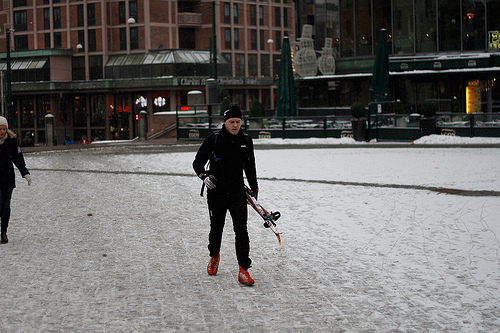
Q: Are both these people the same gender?
A: No, they are both male and female.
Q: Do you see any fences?
A: Yes, there is a fence.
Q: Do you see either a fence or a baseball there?
A: Yes, there is a fence.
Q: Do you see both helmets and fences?
A: No, there is a fence but no helmets.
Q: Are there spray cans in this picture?
A: No, there are no spray cans.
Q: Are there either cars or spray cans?
A: No, there are no spray cans or cars.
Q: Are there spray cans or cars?
A: No, there are no spray cans or cars.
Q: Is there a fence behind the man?
A: Yes, there is a fence behind the man.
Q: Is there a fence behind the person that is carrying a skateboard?
A: Yes, there is a fence behind the man.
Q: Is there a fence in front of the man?
A: No, the fence is behind the man.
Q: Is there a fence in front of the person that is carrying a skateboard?
A: No, the fence is behind the man.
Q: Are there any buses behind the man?
A: No, there is a fence behind the man.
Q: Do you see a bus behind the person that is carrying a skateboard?
A: No, there is a fence behind the man.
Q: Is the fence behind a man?
A: Yes, the fence is behind a man.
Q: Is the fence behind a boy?
A: No, the fence is behind a man.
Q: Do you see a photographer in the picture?
A: No, there are no photographers.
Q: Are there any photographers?
A: No, there are no photographers.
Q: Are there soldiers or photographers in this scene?
A: No, there are no photographers or soldiers.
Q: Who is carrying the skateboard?
A: The man is carrying the skateboard.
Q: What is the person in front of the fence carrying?
A: The man is carrying a skateboard.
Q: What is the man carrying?
A: The man is carrying a skateboard.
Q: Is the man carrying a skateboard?
A: Yes, the man is carrying a skateboard.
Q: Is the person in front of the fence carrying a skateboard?
A: Yes, the man is carrying a skateboard.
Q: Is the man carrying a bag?
A: No, the man is carrying a skateboard.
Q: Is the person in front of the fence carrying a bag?
A: No, the man is carrying a skateboard.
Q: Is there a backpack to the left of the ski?
A: No, there is a man to the left of the ski.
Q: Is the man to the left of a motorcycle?
A: No, the man is to the left of the ski.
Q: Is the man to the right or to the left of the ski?
A: The man is to the left of the ski.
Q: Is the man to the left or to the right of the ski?
A: The man is to the left of the ski.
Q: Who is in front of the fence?
A: The man is in front of the fence.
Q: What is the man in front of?
A: The man is in front of the fence.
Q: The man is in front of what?
A: The man is in front of the fence.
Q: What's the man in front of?
A: The man is in front of the fence.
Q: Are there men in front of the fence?
A: Yes, there is a man in front of the fence.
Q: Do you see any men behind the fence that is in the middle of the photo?
A: No, the man is in front of the fence.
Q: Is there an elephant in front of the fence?
A: No, there is a man in front of the fence.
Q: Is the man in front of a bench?
A: No, the man is in front of the fence.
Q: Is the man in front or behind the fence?
A: The man is in front of the fence.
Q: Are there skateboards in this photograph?
A: Yes, there is a skateboard.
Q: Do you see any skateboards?
A: Yes, there is a skateboard.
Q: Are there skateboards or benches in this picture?
A: Yes, there is a skateboard.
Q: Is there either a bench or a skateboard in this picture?
A: Yes, there is a skateboard.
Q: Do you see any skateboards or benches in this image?
A: Yes, there is a skateboard.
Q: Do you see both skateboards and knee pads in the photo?
A: No, there is a skateboard but no knee pads.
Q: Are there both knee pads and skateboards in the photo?
A: No, there is a skateboard but no knee pads.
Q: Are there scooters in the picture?
A: No, there are no scooters.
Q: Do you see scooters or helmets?
A: No, there are no scooters or helmets.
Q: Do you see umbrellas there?
A: Yes, there is an umbrella.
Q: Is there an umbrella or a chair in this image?
A: Yes, there is an umbrella.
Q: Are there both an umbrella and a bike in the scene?
A: No, there is an umbrella but no bikes.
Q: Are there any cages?
A: No, there are no cages.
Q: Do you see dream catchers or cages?
A: No, there are no cages or dream catchers.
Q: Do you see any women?
A: Yes, there is a woman.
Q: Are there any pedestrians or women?
A: Yes, there is a woman.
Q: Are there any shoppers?
A: No, there are no shoppers.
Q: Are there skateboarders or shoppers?
A: No, there are no shoppers or skateboarders.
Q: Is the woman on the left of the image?
A: Yes, the woman is on the left of the image.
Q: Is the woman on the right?
A: No, the woman is on the left of the image.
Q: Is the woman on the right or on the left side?
A: The woman is on the left of the image.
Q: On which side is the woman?
A: The woman is on the left of the image.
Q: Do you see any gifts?
A: No, there are no gifts.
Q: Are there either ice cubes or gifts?
A: No, there are no gifts or ice cubes.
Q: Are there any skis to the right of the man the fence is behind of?
A: Yes, there is a ski to the right of the man.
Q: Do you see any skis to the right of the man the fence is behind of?
A: Yes, there is a ski to the right of the man.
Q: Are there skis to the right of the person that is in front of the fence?
A: Yes, there is a ski to the right of the man.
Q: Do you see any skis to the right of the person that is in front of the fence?
A: Yes, there is a ski to the right of the man.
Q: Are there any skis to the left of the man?
A: No, the ski is to the right of the man.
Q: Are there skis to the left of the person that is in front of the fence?
A: No, the ski is to the right of the man.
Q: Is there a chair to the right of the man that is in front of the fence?
A: No, there is a ski to the right of the man.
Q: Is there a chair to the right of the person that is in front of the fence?
A: No, there is a ski to the right of the man.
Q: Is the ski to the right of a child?
A: No, the ski is to the right of the man.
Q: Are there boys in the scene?
A: No, there are no boys.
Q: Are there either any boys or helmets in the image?
A: No, there are no boys or helmets.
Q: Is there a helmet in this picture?
A: No, there are no helmets.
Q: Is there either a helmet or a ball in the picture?
A: No, there are no helmets or balls.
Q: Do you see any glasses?
A: No, there are no glasses.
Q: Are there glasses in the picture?
A: No, there are no glasses.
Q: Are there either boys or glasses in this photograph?
A: No, there are no glasses or boys.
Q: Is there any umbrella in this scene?
A: Yes, there is an umbrella.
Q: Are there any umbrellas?
A: Yes, there is an umbrella.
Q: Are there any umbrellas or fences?
A: Yes, there is an umbrella.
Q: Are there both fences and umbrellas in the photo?
A: Yes, there are both an umbrella and a fence.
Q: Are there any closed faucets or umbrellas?
A: Yes, there is a closed umbrella.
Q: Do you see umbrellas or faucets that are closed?
A: Yes, the umbrella is closed.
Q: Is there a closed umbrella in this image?
A: Yes, there is a closed umbrella.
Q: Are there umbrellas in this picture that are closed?
A: Yes, there is an umbrella that is closed.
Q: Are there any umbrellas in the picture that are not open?
A: Yes, there is an closed umbrella.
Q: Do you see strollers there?
A: No, there are no strollers.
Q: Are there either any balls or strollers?
A: No, there are no strollers or balls.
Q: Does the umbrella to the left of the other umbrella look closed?
A: Yes, the umbrella is closed.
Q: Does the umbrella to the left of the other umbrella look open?
A: No, the umbrella is closed.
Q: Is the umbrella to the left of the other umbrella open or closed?
A: The umbrella is closed.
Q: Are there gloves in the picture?
A: Yes, there are gloves.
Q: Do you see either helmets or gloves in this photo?
A: Yes, there are gloves.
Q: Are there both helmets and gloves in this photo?
A: No, there are gloves but no helmets.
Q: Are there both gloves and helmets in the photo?
A: No, there are gloves but no helmets.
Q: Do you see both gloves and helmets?
A: No, there are gloves but no helmets.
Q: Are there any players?
A: No, there are no players.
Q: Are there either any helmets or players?
A: No, there are no players or helmets.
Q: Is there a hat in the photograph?
A: Yes, there is a hat.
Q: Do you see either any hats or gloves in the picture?
A: Yes, there is a hat.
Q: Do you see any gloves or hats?
A: Yes, there is a hat.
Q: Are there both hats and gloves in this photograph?
A: Yes, there are both a hat and gloves.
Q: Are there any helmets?
A: No, there are no helmets.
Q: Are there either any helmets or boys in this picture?
A: No, there are no helmets or boys.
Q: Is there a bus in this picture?
A: No, there are no buses.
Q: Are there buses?
A: No, there are no buses.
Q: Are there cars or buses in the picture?
A: No, there are no buses or cars.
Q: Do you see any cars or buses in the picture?
A: No, there are no buses or cars.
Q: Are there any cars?
A: No, there are no cars.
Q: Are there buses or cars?
A: No, there are no cars or buses.